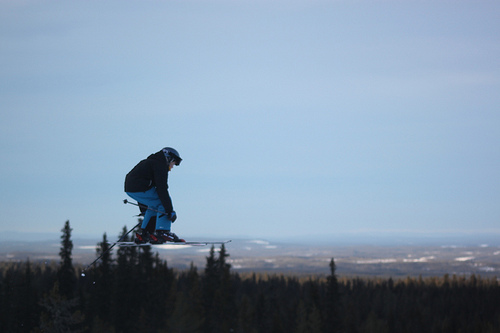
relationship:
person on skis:
[120, 141, 201, 238] [105, 237, 234, 251]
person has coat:
[120, 141, 201, 238] [122, 151, 177, 208]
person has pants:
[120, 141, 201, 238] [122, 184, 181, 237]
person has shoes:
[120, 141, 201, 238] [135, 227, 174, 235]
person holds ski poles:
[120, 141, 201, 238] [86, 195, 185, 272]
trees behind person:
[56, 226, 337, 323] [120, 141, 201, 238]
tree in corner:
[45, 220, 92, 328] [30, 318, 35, 323]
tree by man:
[45, 220, 92, 328] [120, 141, 201, 238]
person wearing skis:
[120, 141, 201, 238] [105, 237, 234, 251]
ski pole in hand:
[123, 198, 169, 218] [167, 210, 181, 221]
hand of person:
[167, 210, 181, 221] [120, 141, 201, 238]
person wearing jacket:
[120, 141, 201, 238] [122, 151, 177, 208]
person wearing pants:
[120, 141, 201, 238] [122, 184, 181, 237]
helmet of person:
[165, 148, 181, 155] [120, 141, 201, 238]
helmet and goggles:
[165, 148, 181, 155] [168, 158, 185, 164]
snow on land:
[365, 257, 429, 264] [247, 246, 499, 277]